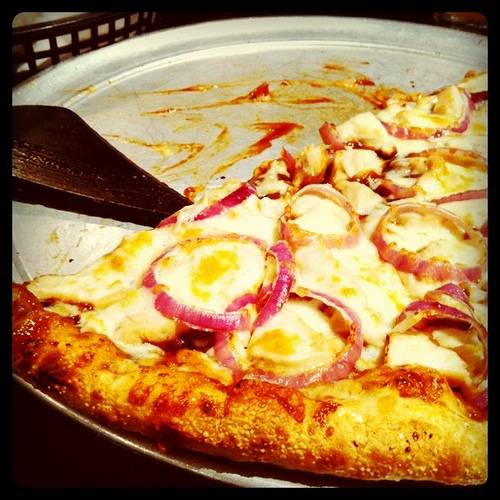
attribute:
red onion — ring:
[141, 237, 295, 338]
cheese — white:
[26, 67, 489, 389]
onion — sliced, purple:
[151, 227, 316, 324]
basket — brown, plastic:
[21, 17, 103, 57]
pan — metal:
[13, 10, 487, 490]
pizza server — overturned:
[11, 105, 194, 214]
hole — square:
[96, 22, 110, 34]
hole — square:
[29, 37, 52, 52]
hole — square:
[126, 12, 141, 27]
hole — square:
[53, 31, 74, 48]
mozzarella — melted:
[68, 45, 481, 418]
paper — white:
[12, 9, 157, 69]